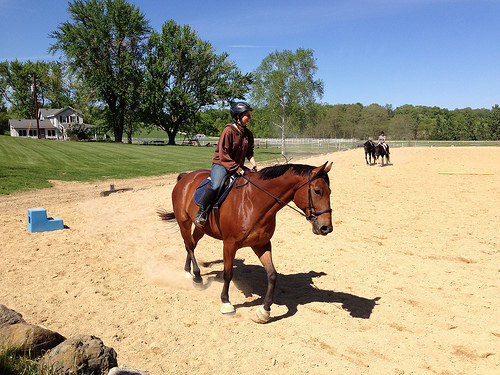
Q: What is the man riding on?
A: A horse.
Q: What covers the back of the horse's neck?
A: A dark mane.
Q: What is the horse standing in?
A: Sand.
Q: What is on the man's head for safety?
A: A helmet.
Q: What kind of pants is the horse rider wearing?
A: Jeans.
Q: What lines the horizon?
A: Trees.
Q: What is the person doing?
A: Riding a horse.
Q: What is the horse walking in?
A: Sand.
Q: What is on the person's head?
A: Helmet.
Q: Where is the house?
A: Left side far back.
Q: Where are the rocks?
A: Left corner.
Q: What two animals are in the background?
A: More horses.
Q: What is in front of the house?
A: Trees.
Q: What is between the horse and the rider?
A: Blue blanket.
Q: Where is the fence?
A: Behind the sand and the lawn.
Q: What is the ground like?
A: Sandy.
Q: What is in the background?
A: Trees.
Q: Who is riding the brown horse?
A: Woman in front.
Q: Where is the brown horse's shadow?
A: On the sand.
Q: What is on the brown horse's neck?
A: Black hair.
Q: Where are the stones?
A: Front left of sand.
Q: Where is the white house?
A: Background on the grass.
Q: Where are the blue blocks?
A: Left part of sand.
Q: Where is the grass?
A: Back left of sand.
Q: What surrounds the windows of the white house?
A: Black shutters.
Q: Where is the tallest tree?
A: Right of the white house.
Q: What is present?
A: A horse.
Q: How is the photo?
A: Clear.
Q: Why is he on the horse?
A: Riding it.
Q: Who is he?
A: A rider.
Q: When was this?
A: Daytime.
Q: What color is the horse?
A: Brown.